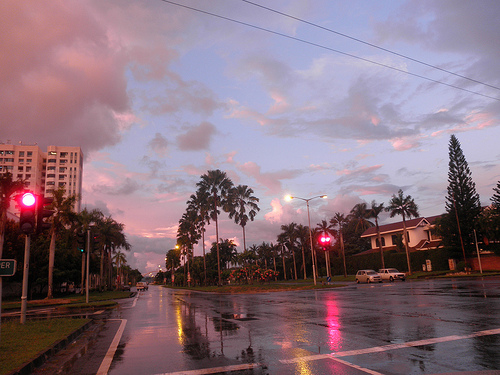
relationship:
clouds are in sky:
[304, 52, 407, 142] [7, 4, 500, 264]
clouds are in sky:
[390, 5, 496, 53] [7, 4, 500, 264]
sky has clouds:
[7, 4, 500, 264] [145, 77, 221, 152]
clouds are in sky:
[116, 193, 183, 237] [7, 4, 500, 264]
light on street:
[287, 193, 330, 285] [30, 261, 499, 369]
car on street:
[378, 265, 405, 284] [30, 261, 499, 369]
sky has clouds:
[7, 4, 500, 264] [420, 81, 500, 135]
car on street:
[354, 267, 373, 284] [30, 261, 499, 369]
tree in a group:
[227, 185, 260, 279] [180, 171, 256, 286]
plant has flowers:
[229, 265, 280, 285] [262, 269, 276, 279]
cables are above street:
[161, 3, 500, 106] [30, 261, 499, 369]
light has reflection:
[319, 231, 333, 249] [325, 285, 344, 374]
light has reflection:
[176, 245, 182, 252] [173, 295, 186, 348]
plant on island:
[229, 265, 280, 285] [162, 245, 328, 296]